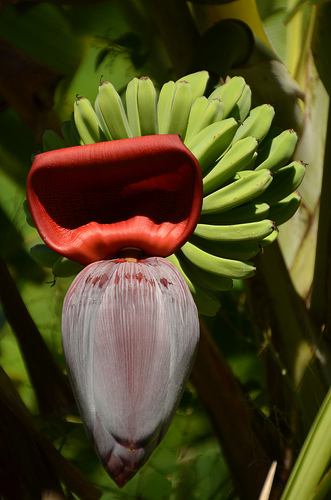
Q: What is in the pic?
A: Bananas.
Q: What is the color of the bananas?
A: Green.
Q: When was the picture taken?
A: During the day.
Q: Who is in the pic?
A: No one.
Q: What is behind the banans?
A: Tree.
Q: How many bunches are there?
A: 1.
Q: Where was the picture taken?
A: At a garden.